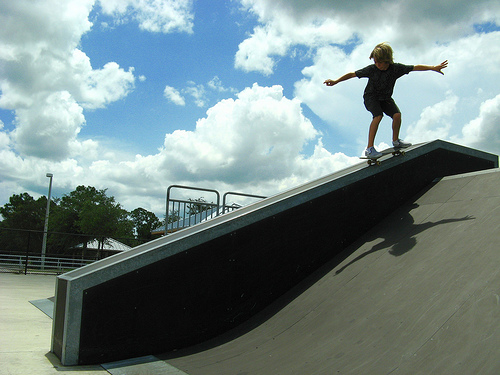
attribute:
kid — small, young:
[319, 40, 451, 158]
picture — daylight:
[1, 1, 500, 374]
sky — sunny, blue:
[3, 2, 499, 230]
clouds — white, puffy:
[1, 1, 141, 162]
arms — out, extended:
[324, 60, 450, 86]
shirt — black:
[357, 61, 414, 97]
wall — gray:
[41, 139, 497, 365]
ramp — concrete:
[27, 141, 499, 374]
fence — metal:
[0, 252, 99, 273]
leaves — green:
[0, 185, 159, 261]